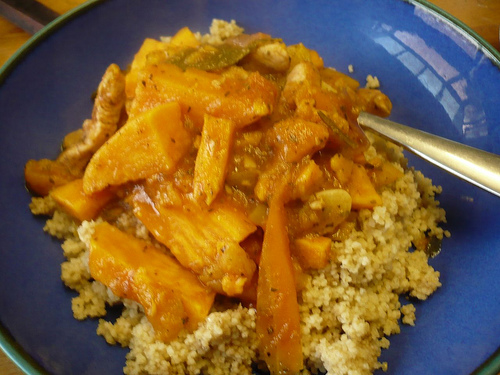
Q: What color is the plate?
A: Blue.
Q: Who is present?
A: No one.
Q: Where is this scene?
A: In a dining room.